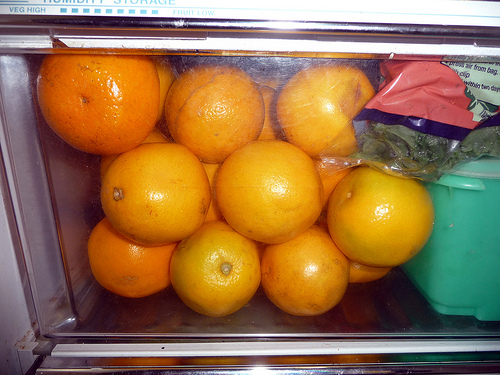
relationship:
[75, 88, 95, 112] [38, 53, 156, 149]
spot on fruit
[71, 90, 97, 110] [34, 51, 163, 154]
spot on fruit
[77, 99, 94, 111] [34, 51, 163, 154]
spot on fruit